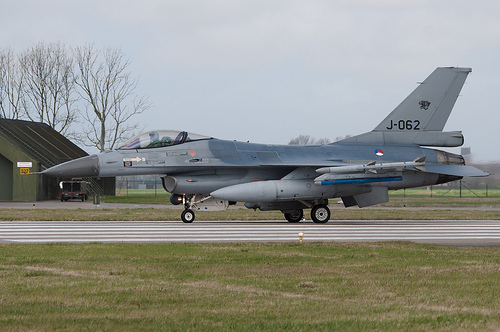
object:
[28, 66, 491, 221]
fighter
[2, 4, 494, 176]
sky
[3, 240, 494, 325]
patches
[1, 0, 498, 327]
picture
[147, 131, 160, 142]
helmet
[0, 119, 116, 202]
building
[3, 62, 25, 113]
tree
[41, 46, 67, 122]
tree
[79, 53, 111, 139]
tree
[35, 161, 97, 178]
nose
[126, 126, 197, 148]
cockpit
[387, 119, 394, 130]
letter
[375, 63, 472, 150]
tail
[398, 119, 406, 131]
number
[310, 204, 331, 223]
wheel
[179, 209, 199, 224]
wheel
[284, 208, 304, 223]
wheel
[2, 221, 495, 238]
runway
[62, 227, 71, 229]
line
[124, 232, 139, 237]
line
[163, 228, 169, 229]
line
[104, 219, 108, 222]
line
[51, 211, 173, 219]
grass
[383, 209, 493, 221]
grass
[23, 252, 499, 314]
grass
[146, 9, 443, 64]
sky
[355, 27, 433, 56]
cloud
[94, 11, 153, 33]
cloud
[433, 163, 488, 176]
wing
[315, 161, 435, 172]
missile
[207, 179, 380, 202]
missile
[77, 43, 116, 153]
leafless tree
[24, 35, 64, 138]
leafless tree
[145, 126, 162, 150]
pilot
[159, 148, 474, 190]
wing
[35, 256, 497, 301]
ground